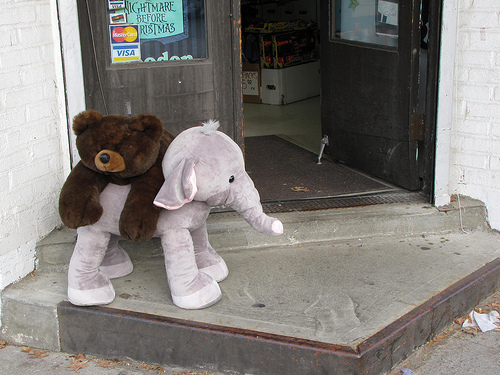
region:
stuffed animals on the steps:
[10, 10, 453, 295]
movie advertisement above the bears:
[82, 0, 254, 289]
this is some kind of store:
[238, 5, 438, 212]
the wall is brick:
[6, 5, 186, 215]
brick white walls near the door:
[355, 1, 498, 218]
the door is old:
[319, 5, 459, 230]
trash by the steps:
[371, 224, 496, 374]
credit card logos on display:
[95, 3, 158, 89]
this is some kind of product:
[254, 19, 322, 82]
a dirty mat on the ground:
[229, 78, 402, 235]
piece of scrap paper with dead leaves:
[464, 294, 499, 341]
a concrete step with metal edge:
[0, 278, 480, 374]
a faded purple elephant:
[148, 124, 288, 314]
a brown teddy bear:
[54, 103, 161, 246]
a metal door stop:
[301, 120, 353, 181]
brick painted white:
[5, 14, 73, 276]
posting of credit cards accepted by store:
[107, 1, 149, 67]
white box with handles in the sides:
[258, 54, 322, 116]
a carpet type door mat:
[239, 129, 386, 206]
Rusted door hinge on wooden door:
[384, 105, 434, 152]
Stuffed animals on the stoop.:
[43, 90, 342, 338]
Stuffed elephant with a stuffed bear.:
[48, 98, 337, 327]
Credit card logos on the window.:
[100, 5, 182, 94]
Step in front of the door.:
[22, 273, 243, 373]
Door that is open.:
[223, 13, 488, 212]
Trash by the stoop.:
[442, 310, 493, 332]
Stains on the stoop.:
[388, 215, 473, 302]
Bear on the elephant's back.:
[17, 82, 193, 242]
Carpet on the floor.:
[247, 118, 420, 238]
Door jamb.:
[311, 89, 379, 177]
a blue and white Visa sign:
[109, 40, 145, 64]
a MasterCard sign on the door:
[109, 23, 141, 43]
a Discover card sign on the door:
[107, 7, 129, 24]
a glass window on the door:
[106, 0, 211, 67]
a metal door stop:
[312, 131, 335, 165]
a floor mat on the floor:
[239, 129, 395, 202]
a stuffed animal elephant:
[61, 115, 286, 311]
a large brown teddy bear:
[53, 105, 178, 249]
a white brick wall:
[1, 2, 67, 287]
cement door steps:
[2, 192, 496, 374]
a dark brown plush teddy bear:
[53, 114, 163, 238]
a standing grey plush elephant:
[68, 125, 278, 312]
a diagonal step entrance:
[4, 194, 496, 371]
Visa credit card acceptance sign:
[106, 42, 144, 67]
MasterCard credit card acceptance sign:
[107, 25, 139, 41]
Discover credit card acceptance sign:
[107, 11, 124, 25]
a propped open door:
[313, 4, 433, 189]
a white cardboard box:
[256, 59, 316, 104]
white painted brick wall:
[450, 0, 496, 205]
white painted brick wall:
[0, 6, 64, 251]